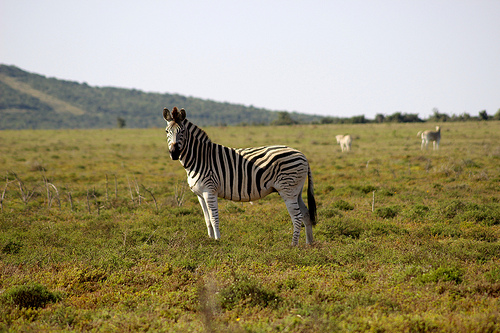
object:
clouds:
[419, 25, 475, 92]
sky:
[2, 0, 500, 122]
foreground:
[2, 120, 500, 333]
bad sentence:
[376, 247, 395, 274]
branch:
[125, 171, 159, 216]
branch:
[35, 158, 59, 206]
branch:
[12, 172, 35, 204]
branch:
[174, 181, 186, 207]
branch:
[1, 176, 20, 209]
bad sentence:
[331, 176, 369, 211]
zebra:
[161, 106, 317, 246]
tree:
[270, 110, 297, 126]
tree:
[375, 113, 385, 123]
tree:
[478, 109, 488, 120]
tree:
[311, 117, 319, 125]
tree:
[117, 115, 126, 129]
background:
[0, 57, 499, 131]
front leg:
[196, 189, 213, 234]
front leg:
[203, 182, 220, 236]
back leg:
[272, 175, 306, 233]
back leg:
[297, 186, 311, 229]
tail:
[306, 160, 318, 229]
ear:
[177, 108, 186, 121]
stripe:
[253, 150, 296, 187]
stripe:
[236, 154, 246, 201]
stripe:
[223, 148, 235, 197]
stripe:
[210, 146, 222, 184]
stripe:
[290, 192, 298, 215]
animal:
[335, 134, 353, 152]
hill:
[0, 63, 348, 128]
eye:
[177, 128, 181, 134]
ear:
[162, 107, 171, 123]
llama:
[417, 125, 442, 150]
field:
[1, 115, 500, 332]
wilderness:
[0, 63, 499, 333]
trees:
[0, 111, 47, 129]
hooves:
[207, 237, 315, 248]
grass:
[0, 119, 499, 333]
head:
[162, 106, 189, 160]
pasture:
[0, 118, 499, 333]